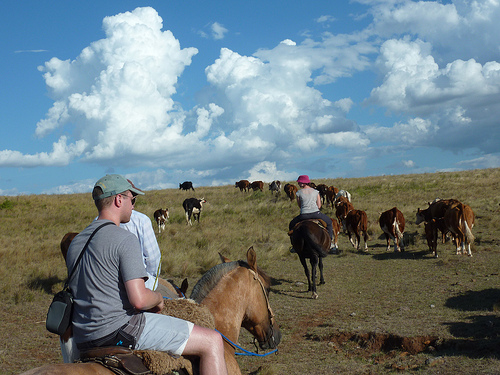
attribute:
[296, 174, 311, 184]
hat —  red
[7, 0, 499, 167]
sky — blue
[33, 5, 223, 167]
puffiest cloud — whitest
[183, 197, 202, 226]
cow — white, black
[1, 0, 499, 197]
sky — blue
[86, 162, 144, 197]
hat — green